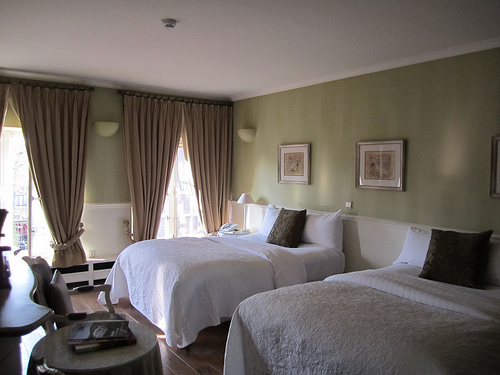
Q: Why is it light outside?
A: Sun.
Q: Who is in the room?
A: Nobody.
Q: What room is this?
A: Bedroom.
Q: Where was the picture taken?
A: Hotel.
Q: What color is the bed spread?
A: White.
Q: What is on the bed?
A: Pillows.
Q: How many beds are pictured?
A: 2.